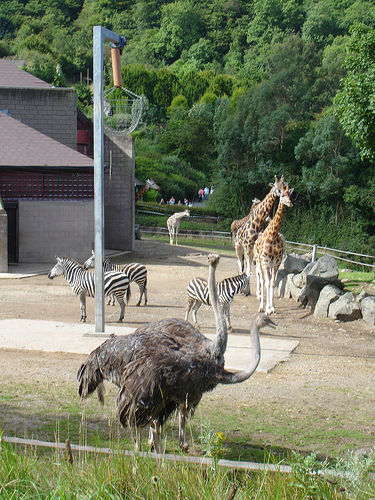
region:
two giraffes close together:
[227, 176, 310, 351]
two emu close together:
[92, 262, 266, 407]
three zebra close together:
[24, 251, 255, 302]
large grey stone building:
[0, 83, 121, 269]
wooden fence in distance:
[190, 221, 374, 291]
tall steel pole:
[85, 29, 111, 335]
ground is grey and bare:
[278, 342, 333, 438]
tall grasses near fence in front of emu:
[5, 444, 223, 498]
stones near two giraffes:
[285, 253, 347, 321]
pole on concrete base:
[1, 302, 263, 379]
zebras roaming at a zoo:
[47, 248, 251, 332]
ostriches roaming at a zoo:
[79, 253, 278, 453]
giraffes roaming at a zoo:
[230, 174, 295, 317]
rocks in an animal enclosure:
[283, 253, 373, 323]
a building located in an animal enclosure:
[0, 58, 132, 278]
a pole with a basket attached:
[91, 25, 143, 334]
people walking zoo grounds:
[158, 184, 216, 208]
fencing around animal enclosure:
[136, 221, 374, 268]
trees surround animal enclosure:
[145, 2, 373, 172]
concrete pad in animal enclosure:
[0, 316, 299, 373]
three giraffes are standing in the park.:
[230, 177, 299, 283]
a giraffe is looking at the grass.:
[150, 206, 198, 241]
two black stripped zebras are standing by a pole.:
[44, 242, 155, 317]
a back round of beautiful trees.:
[151, 4, 363, 171]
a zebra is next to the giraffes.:
[175, 275, 254, 320]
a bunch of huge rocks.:
[278, 252, 371, 324]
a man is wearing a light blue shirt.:
[202, 185, 210, 194]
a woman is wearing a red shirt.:
[197, 186, 203, 198]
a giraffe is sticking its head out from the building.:
[132, 173, 160, 208]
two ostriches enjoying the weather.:
[78, 252, 278, 470]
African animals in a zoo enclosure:
[4, 159, 374, 469]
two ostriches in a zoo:
[86, 244, 280, 470]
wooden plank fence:
[15, 423, 345, 487]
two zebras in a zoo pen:
[38, 252, 156, 318]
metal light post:
[81, 14, 150, 335]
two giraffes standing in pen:
[219, 170, 303, 322]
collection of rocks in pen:
[287, 242, 374, 326]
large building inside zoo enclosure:
[3, 50, 144, 281]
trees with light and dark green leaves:
[145, 11, 361, 168]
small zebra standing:
[179, 267, 254, 329]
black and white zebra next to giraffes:
[182, 264, 252, 317]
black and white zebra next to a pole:
[60, 251, 125, 303]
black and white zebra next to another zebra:
[120, 243, 147, 281]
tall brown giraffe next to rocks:
[252, 180, 292, 287]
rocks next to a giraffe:
[319, 250, 353, 319]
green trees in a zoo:
[229, 20, 334, 145]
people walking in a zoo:
[160, 178, 217, 198]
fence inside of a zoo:
[189, 219, 213, 245]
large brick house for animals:
[17, 145, 80, 253]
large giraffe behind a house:
[143, 161, 164, 257]